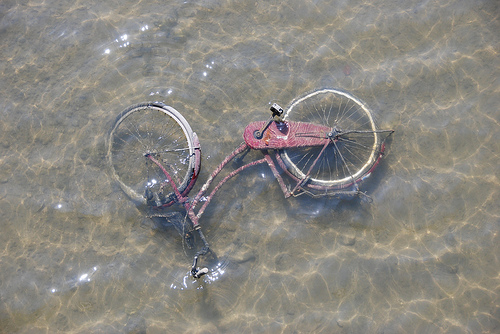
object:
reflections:
[74, 27, 246, 99]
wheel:
[277, 84, 384, 190]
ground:
[398, 148, 500, 325]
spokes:
[113, 108, 190, 180]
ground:
[317, 211, 500, 326]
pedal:
[254, 103, 283, 139]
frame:
[143, 102, 397, 279]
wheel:
[102, 100, 202, 208]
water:
[0, 0, 499, 332]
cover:
[243, 119, 340, 149]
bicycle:
[100, 86, 396, 279]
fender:
[289, 172, 375, 203]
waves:
[272, 235, 493, 326]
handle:
[195, 267, 209, 279]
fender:
[142, 131, 204, 209]